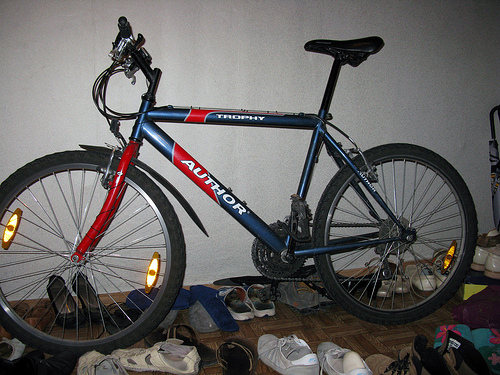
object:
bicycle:
[1, 16, 476, 354]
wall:
[0, 0, 499, 303]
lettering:
[179, 157, 246, 218]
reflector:
[143, 249, 161, 293]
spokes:
[53, 173, 82, 231]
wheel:
[1, 149, 187, 357]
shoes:
[470, 326, 499, 375]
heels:
[46, 274, 85, 327]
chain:
[251, 216, 392, 285]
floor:
[0, 257, 499, 375]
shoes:
[313, 342, 372, 374]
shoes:
[110, 337, 200, 375]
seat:
[305, 34, 386, 69]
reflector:
[2, 207, 25, 252]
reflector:
[441, 237, 458, 273]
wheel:
[312, 142, 479, 323]